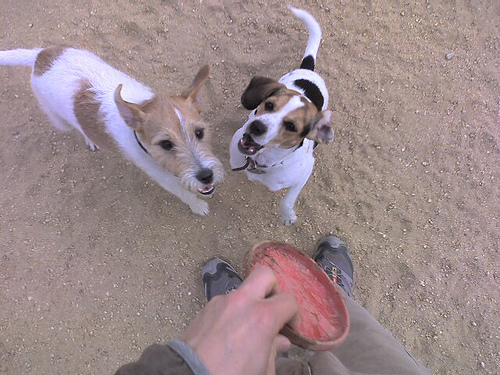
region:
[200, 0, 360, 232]
this is a dog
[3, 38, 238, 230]
this is a dog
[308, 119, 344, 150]
this is a ear of a dog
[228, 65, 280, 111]
this is a ear of a dog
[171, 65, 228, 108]
this is a ear of a dog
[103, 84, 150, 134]
this is a ear of a dog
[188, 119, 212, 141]
this is a eye of a dog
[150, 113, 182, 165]
this is a eye of a dog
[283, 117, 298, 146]
this is a eye of a dog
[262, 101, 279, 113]
this is a eye of a dog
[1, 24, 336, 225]
Two dogs on the dirt.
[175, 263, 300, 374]
Part of a hand and fingers.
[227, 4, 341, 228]
A dog jumping up.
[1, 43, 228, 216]
A brown and white dog.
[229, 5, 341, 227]
A dog with a collar.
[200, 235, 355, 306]
A pair of brown shoes.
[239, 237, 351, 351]
A red clay plate.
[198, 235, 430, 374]
Brown pants and shoes.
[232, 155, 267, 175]
A collar and tag.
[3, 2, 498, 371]
Brown dirt and pebbles.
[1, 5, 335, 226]
A pair of two dogs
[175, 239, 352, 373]
A frisbee in a hand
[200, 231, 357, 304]
A pair of shoes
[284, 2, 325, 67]
Tail of a dog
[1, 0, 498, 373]
Brown dirt on the ground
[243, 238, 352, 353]
A dirty red frisbee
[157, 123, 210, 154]
Two black eyes of a dog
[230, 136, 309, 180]
Collar around dog's neck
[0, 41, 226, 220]
A brown and white dog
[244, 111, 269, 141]
Black nose on dog's face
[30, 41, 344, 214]
two dogs looking at man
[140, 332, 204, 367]
man has brown jacket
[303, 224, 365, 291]
man has black shoes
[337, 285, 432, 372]
man has grey pants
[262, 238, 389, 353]
man holds red disc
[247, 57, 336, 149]
dog has dark brown ears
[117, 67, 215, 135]
dog has light brown ears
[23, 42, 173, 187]
dog has light brown spots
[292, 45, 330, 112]
dog has black spots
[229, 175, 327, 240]
dogs have white paws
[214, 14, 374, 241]
White and black dog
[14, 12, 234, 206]
White and brown dog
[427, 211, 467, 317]
Small pebbles in the dirt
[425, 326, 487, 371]
Small pebbles in the dirt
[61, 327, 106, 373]
Small pebbles in the dirt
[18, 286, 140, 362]
Small pebbles in the dirt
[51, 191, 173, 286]
Small pebbles in the dirt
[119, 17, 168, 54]
Small pebbles in the dirt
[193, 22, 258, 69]
Small pebbles in the dirt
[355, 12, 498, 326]
Small pebbles in the dirt